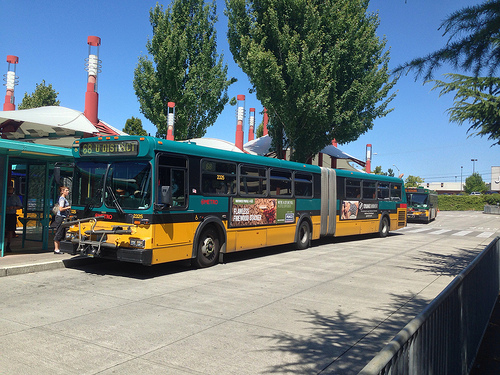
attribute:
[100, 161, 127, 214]
wiper — black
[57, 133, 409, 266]
bus — windshield, yellow, blueish green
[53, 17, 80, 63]
sky — clear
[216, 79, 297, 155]
pole — red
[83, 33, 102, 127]
part — red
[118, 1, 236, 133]
tree — tall, green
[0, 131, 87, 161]
blue trim — light blue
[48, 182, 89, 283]
woman — boarding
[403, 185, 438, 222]
bus — yellow, blueish green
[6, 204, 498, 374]
driveway — large, white, tile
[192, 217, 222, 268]
tire — black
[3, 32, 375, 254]
bus station — large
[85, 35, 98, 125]
pole — red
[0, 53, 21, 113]
pole — red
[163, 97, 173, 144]
pole — red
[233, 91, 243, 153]
pole — red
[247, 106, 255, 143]
pole — red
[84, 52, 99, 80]
part — white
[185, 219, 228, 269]
tire — black, round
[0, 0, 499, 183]
sky — clear, blue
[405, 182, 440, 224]
bus — behind, green, yellow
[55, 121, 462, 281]
bus — long, blue, yellow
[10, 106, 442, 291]
bus — long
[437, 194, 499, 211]
bushes — green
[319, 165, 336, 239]
connector — grey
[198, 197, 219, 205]
lettering — red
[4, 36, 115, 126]
red poles — sticking out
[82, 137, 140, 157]
sign — lighted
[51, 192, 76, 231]
shirt — gray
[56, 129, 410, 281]
bus — yellow, peacock green